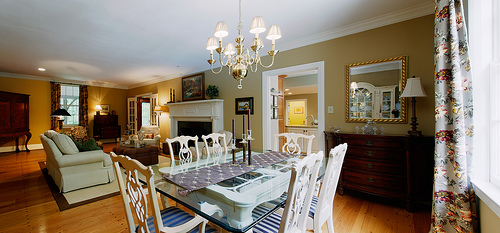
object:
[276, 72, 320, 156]
door frame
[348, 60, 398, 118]
mirror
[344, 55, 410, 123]
frame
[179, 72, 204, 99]
frame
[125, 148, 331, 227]
room table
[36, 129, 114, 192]
sofa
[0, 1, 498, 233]
room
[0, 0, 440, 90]
ceiling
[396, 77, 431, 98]
lampshade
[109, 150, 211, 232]
chair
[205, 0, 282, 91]
chandelier